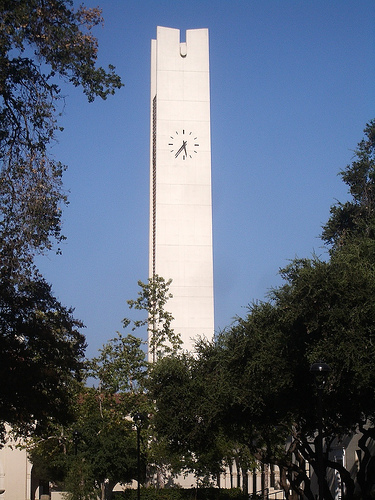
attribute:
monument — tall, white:
[146, 22, 216, 493]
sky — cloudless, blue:
[220, 19, 345, 174]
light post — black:
[130, 407, 147, 487]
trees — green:
[157, 340, 296, 491]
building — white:
[303, 415, 364, 487]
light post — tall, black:
[301, 358, 330, 490]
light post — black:
[71, 429, 82, 490]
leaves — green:
[5, 15, 132, 490]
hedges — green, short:
[113, 487, 243, 497]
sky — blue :
[232, 59, 309, 172]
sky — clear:
[233, 77, 316, 181]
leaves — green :
[239, 340, 366, 403]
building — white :
[147, 20, 219, 497]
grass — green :
[150, 487, 197, 497]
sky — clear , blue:
[249, 144, 326, 222]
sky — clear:
[269, 115, 317, 182]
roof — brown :
[65, 382, 136, 412]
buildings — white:
[115, 22, 275, 496]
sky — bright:
[243, 124, 311, 196]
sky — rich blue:
[230, 44, 311, 155]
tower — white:
[125, 131, 233, 283]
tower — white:
[140, 165, 215, 274]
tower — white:
[145, 120, 229, 254]